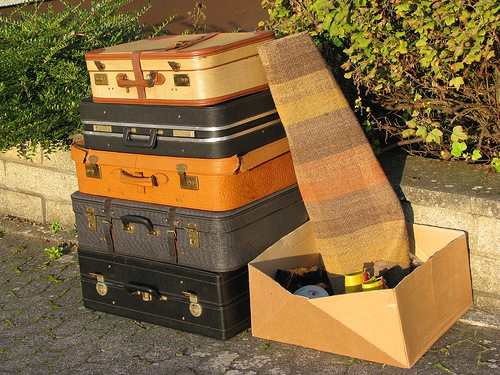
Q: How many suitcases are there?
A: 5.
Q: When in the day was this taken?
A: Daytime.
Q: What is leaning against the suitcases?
A: Rug.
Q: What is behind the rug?
A: Bushes.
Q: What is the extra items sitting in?
A: A box.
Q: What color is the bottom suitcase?
A: Black.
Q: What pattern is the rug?
A: Striped.